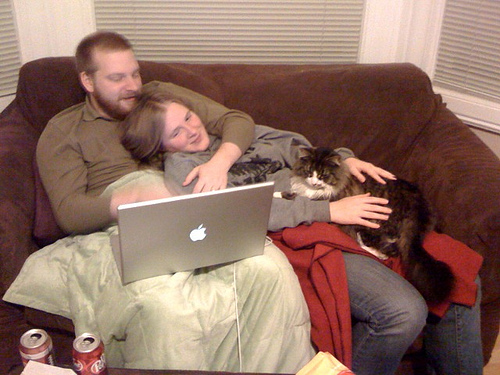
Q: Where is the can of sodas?
A: On the table.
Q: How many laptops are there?
A: 1.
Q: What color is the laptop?
A: Silver.